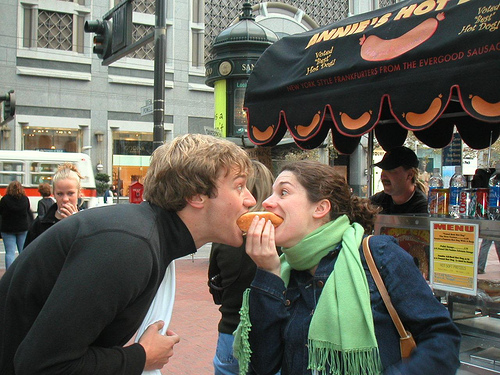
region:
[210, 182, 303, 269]
The people are sharing food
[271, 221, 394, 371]
The girl has a scarf on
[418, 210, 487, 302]
This is the menu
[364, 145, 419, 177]
The man has a hat on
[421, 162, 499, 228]
The drinks are lined up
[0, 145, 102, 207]
A vehicle is in the back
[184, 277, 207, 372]
The ground is bricks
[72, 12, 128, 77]
This is a traffic light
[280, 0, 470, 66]
This is Annie's Hotdog stand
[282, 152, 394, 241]
The girl's hair is pulled back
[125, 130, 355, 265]
People enjoying food together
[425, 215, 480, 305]
Menu for customers to read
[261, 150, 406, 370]
Woman wearing a scarf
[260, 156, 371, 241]
Woman with brunette hair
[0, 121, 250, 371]
Man wearing a turtleneck shirt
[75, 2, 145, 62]
Traffic light over a street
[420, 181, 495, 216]
Different cans of soda lined up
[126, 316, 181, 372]
Hand of a person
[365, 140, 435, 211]
Man wearing black hat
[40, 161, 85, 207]
Female with blond hair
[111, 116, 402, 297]
two people in an awkward pose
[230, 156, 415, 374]
woman in a green scarf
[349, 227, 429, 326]
strap on woman's shoulder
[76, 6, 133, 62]
traffic light with shade on the red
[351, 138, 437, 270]
man in a baseball cap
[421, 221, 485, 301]
sign on store window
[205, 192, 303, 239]
hot dog being shared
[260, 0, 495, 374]
store that sells hot dogs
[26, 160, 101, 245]
girl with hand to her mouth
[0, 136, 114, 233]
bus on the street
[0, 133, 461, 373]
blonde hair man and a dark haired woman sharing a hotdog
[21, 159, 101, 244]
a blonde hair woman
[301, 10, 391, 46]
yellow text reading Annie's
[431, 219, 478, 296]
menu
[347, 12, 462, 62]
hot dog graphic on a sign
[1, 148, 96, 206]
white and red bus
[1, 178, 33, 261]
woman wearing a black coat and jeans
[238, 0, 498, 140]
black sign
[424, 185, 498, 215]
bunch of soda cans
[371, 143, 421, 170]
black hat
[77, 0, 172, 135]
A stoplight.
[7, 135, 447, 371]
Two people eating a hot dog at the same time.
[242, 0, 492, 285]
A hot dog vendor.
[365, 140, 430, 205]
The man has a mustache.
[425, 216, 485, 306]
A menu is attached to the window.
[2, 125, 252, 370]
The man is wearing a turtleneck.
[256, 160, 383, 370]
The woman is wearing a green scarf.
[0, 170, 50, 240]
People waiting to cross the street.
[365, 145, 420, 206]
The man is wearing a black hat.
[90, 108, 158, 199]
A storefront.